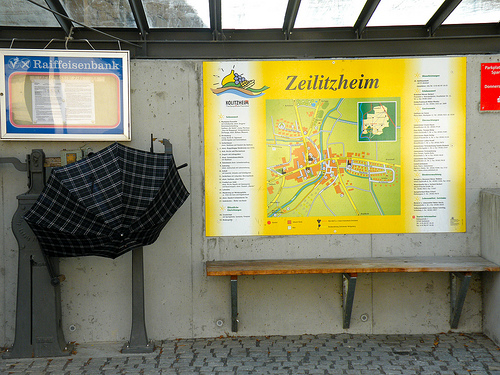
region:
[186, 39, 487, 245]
a yellow sign with black letters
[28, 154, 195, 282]
an open black umbrella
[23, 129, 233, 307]
a black and white umbrella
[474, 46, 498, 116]
a red and white sign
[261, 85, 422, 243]
a map on a sign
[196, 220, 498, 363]
a bench against the wall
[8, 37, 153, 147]
a blue and white sign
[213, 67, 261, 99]
picture of fruit on a sign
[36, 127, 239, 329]
an upside down umbrella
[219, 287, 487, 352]
green bars under bench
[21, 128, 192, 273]
a hanging umbrella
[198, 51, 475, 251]
a large yellow map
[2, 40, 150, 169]
a protective glass case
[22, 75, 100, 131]
papers displayed inside a case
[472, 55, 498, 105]
the edge of a bright orange sign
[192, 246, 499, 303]
an empty wooden bench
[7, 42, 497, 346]
a concrete wall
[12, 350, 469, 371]
the edge of a cobblestone street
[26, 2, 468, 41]
a row of glass skylights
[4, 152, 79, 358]
a heavy metal device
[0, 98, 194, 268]
the umbrella is open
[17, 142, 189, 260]
the umbrella is plaid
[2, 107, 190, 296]
the umbrella is dark colored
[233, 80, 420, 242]
a sign of a map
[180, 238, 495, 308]
the bench is brown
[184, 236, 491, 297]
the bench is made of wood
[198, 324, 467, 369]
the ground is grey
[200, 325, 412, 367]
the ground is made of bricks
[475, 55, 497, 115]
the sign is red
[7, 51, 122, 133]
a reflection of objects in the sign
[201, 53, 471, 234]
a street map of a town in germany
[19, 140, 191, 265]
black and grey plaid umbrella is hanging upside down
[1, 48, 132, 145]
information poster in a glass fronted box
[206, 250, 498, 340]
a bench is fixed to a wall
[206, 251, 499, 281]
wooden bench surface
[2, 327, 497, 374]
grey cobbled ground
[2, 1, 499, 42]
glass paneled roof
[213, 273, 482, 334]
three metal brackets support a bench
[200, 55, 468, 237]
poster is bright yellow and white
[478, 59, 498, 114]
red sign on the wall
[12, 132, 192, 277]
black and gray plaid print umbrella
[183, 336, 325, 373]
cobblestone ground with dark grout in between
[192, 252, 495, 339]
small bench mounted to the wall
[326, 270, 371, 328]
metal bracket mounted to the wall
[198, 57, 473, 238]
yellow and white sign with map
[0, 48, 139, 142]
blue sign with paper posted inside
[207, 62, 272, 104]
fruit and sun in logo on sign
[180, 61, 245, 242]
banner mounted on a cement wall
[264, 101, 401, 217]
map on the banner sign of the area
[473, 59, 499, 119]
red and white sign on concrete wall